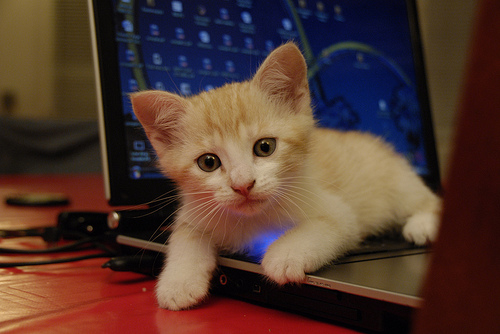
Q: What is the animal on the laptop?
A: Cat.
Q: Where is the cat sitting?
A: On the laptop.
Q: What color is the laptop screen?
A: Blue.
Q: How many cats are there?
A: 1.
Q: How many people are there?
A: 0.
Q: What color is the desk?
A: Red.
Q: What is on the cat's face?
A: Whiskers.